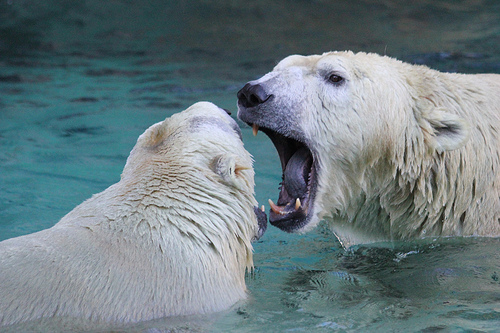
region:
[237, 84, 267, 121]
Bear has black nose.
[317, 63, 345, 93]
Bear has dark eye.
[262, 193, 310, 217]
Bear has sharp teeth.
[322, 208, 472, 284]
Bear is emerged in water.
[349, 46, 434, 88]
Bear has white head.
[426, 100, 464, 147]
Bear has white ear.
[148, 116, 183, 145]
Bear has white head.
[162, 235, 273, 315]
Bear is standing in water.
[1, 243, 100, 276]
Bear has white back.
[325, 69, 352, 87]
the eye of a polar bear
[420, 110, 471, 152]
the ear of the polar bear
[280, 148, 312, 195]
the polar bear's tongue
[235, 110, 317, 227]
the open mouth of a polar bear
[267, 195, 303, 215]
a polar bear's teeth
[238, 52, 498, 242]
a polar bear with its mouth open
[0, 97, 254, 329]
a polar bear in the water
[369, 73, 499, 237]
the wet fur of a polar bear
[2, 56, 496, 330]
two polar bears in the water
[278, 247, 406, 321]
the reflection of the polar bear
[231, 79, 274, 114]
NOSE OF POLAR BEAR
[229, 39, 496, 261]
POLAR BEAR WITH OPEN MOUTH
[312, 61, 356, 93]
EYE OF POLAR BEAR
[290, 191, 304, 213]
SHARP TOOTH OF BEAR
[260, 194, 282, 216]
SHARP TOOTH OF POLAR BEAR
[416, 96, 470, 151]
EAR OF POLAR BEAR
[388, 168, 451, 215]
WET FUR OF POLAR BEAR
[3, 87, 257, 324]
BOLAR BEAR ABOUT TO BE ATTACKED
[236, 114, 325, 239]
OPEN MOUTH OF POLAR BEAR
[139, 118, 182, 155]
EAR OF POLAR BEAR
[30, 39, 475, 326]
Two polar bear in water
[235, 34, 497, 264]
a large polar bear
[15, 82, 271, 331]
a small polar bear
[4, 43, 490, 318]
two polar bears fighting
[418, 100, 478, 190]
a polar bear's left ear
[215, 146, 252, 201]
a polar bear's right ear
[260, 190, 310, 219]
a polar bear's bottom fangs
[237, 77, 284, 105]
a polar bear's nose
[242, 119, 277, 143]
a polar bear's top right fang